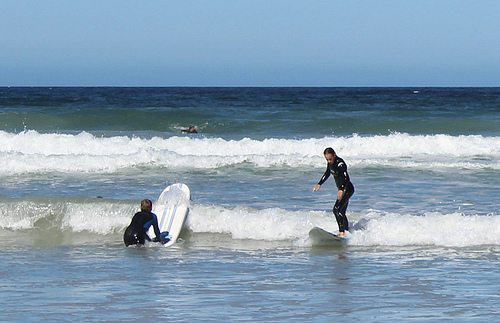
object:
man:
[122, 199, 170, 249]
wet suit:
[122, 210, 161, 245]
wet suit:
[317, 157, 356, 235]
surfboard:
[146, 182, 192, 250]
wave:
[0, 126, 499, 247]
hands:
[309, 185, 321, 193]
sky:
[1, 2, 499, 86]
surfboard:
[303, 226, 350, 246]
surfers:
[312, 147, 356, 238]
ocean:
[0, 86, 499, 323]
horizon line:
[5, 86, 498, 87]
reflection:
[299, 243, 348, 257]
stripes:
[148, 181, 190, 248]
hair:
[322, 146, 337, 167]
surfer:
[179, 124, 203, 135]